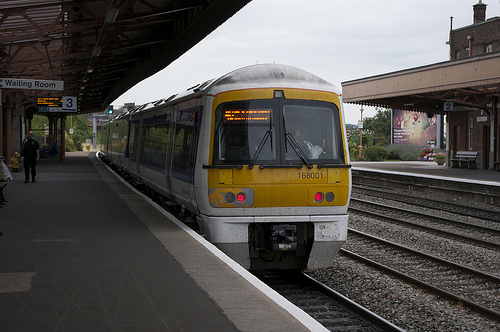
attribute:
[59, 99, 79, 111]
sign — white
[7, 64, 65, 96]
sign — white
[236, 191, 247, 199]
headlight — round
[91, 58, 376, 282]
train — yellow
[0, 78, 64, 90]
sign — black, white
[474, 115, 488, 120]
sign — white, black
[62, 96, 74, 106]
sign — white, black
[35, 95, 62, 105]
sign — white, black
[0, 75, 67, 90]
sign — white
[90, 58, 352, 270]
train — yellow, white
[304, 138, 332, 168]
bag — white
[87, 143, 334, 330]
curb — white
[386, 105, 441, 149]
poster — purple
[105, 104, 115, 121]
signal light — green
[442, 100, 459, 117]
sign — white, black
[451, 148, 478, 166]
bench — wooden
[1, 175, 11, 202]
bench — wooden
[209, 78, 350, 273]
front — yellow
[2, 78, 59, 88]
letters — blue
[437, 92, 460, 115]
number — black